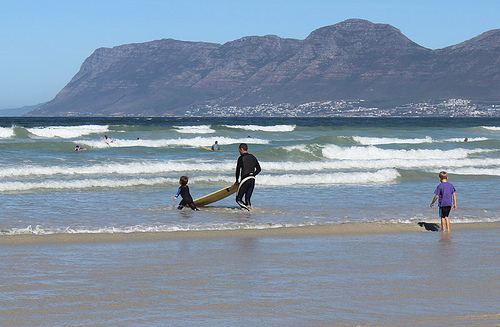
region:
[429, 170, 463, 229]
Child in the ocean.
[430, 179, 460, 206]
Child wearing purple shirt.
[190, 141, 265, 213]
Man with surf board.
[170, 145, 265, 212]
Man and child in the water.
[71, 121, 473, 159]
People swimming in the ocean.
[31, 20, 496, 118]
Mountains in the background.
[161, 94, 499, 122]
Buildings in the distance.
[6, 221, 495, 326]
Shallow water above the beach.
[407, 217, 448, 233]
Dog in the water.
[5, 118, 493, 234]
Waves coming in on the beach.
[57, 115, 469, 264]
people enjoying the beach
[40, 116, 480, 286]
plenty people enjoying the beach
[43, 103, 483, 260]
multiple people enjoying the beach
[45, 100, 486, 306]
some people enjoying the beach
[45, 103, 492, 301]
lots of people enjoying the beach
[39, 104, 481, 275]
happy people enjoying the beach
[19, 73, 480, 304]
people vacationing on the beach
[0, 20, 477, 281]
people enjoying the beach during daytime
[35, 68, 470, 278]
people enjoying the beautiful beach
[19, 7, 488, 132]
nice mountain view at the beach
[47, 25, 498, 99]
majestic mountain range covered in forest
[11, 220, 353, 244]
ocean wave receding on sand bar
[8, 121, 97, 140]
green and white wave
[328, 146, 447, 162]
ocean foam of white wave crest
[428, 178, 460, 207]
purple shirt being worn by a boy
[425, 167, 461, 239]
boy standing on beach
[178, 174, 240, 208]
white surfboard held by a man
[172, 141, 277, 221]
father and son with a surfboard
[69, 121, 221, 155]
humans enjoying surfing in the ocean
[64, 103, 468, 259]
a sunny and pleasant day at the beach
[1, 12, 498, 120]
view of mountains in background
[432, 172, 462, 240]
boy in periwinkle shirt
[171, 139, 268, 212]
older man helping child with surfboard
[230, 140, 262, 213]
man in black and white wetsuit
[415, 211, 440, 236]
shadow of boy in sandy water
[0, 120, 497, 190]
white waves in the background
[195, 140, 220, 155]
man on yellow surfboard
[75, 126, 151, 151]
people swimming in the background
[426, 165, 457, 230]
boy with blond hair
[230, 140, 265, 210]
black wet suit with white stripe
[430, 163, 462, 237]
A boy in a purple shirt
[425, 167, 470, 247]
A boy stands on the shore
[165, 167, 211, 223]
A boy with a black swim suit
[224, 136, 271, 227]
A man wearing a black and white swimsuit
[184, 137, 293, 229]
The man is holding the end of a surf board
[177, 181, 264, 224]
The surf board is white and black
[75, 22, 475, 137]
Mountains next to the ocean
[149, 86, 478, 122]
White buildings across the mountain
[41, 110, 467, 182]
People swimming in the waves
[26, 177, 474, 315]
A beige sandy beach